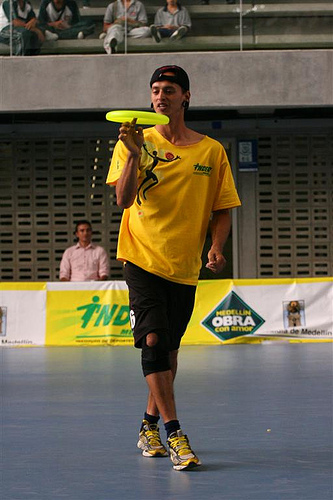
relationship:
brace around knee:
[140, 327, 172, 378] [143, 330, 159, 348]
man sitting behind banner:
[59, 220, 110, 281] [1, 276, 332, 347]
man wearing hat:
[100, 64, 242, 473] [148, 64, 190, 90]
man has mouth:
[100, 64, 242, 473] [156, 101, 169, 111]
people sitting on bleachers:
[1, 1, 192, 55] [3, 2, 332, 48]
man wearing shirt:
[59, 220, 110, 281] [58, 239, 111, 282]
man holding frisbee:
[100, 64, 242, 473] [104, 107, 171, 126]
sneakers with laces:
[135, 419, 199, 472] [146, 428, 188, 453]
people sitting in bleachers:
[1, 1, 192, 55] [3, 2, 332, 48]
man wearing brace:
[100, 64, 242, 473] [140, 327, 172, 378]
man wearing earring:
[100, 64, 242, 473] [181, 99, 191, 110]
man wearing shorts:
[100, 64, 242, 473] [122, 260, 195, 349]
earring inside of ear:
[181, 99, 191, 110] [181, 88, 191, 110]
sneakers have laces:
[135, 419, 199, 472] [146, 428, 188, 453]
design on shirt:
[133, 139, 180, 208] [105, 127, 240, 286]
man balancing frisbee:
[100, 64, 242, 473] [104, 107, 171, 126]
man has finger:
[100, 64, 242, 473] [131, 114, 139, 134]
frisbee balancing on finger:
[104, 107, 171, 126] [131, 114, 139, 134]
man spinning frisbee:
[100, 64, 242, 473] [104, 107, 171, 126]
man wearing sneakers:
[100, 64, 242, 473] [135, 419, 199, 472]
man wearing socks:
[100, 64, 242, 473] [142, 409, 180, 432]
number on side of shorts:
[128, 304, 137, 329] [122, 260, 195, 349]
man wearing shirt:
[100, 64, 242, 473] [105, 127, 240, 286]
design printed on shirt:
[133, 139, 180, 208] [105, 127, 240, 286]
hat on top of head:
[148, 64, 190, 90] [149, 62, 193, 118]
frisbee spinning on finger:
[104, 107, 171, 126] [131, 114, 139, 134]